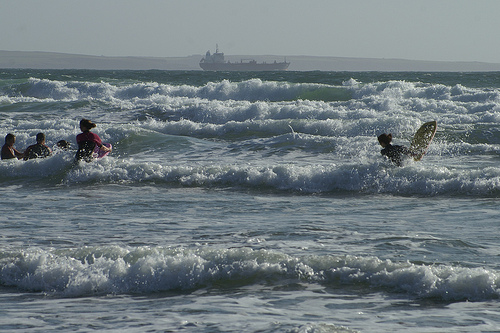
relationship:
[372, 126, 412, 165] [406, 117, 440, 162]
person on boogie board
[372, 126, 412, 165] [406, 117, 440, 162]
person on a surfboard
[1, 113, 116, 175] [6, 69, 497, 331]
people playing in water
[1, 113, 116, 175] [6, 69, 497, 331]
people playing in ocean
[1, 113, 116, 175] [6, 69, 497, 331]
people riding waves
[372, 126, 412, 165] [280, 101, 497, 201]
surfer rides a wave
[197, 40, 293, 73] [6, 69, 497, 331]
ship sails ocean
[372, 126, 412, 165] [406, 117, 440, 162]
woman on top boogie board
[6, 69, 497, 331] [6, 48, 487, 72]
waves rolling in shore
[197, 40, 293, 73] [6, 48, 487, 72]
tanker in distance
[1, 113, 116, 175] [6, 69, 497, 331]
group playing in waves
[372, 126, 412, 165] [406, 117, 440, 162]
woman on pink boogie board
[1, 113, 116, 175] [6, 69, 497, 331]
people getting wet in ocean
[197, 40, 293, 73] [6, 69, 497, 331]
ship in distance ocean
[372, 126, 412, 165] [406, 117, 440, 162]
woman has surfboard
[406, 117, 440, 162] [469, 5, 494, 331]
surfboard on left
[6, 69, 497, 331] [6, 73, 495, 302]
water sets of waves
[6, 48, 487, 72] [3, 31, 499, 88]
hills in background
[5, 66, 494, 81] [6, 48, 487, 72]
water calm in distance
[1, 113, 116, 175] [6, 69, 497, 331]
people in water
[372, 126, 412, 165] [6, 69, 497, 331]
person standing in water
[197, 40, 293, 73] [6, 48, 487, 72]
ship in distance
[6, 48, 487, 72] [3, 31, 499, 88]
land far in distance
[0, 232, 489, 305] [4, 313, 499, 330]
wave rolling into shore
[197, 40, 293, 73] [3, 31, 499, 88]
ship in background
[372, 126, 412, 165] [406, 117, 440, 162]
woman on pink surfboard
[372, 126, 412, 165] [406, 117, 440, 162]
woman holding yellow surfboard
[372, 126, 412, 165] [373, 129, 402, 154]
woman wears ponytail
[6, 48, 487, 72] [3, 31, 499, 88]
hills in far background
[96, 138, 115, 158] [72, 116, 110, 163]
surfboard under woman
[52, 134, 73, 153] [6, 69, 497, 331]
man submerged in water